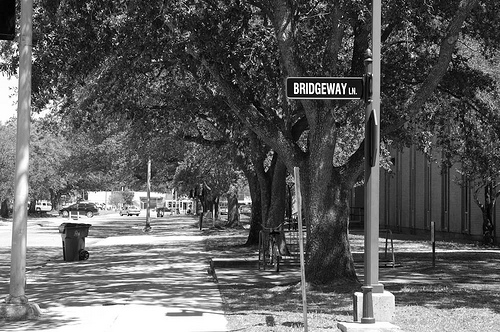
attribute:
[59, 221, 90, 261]
can — black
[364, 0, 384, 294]
post — metal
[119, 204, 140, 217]
car — parked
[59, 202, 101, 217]
car — parked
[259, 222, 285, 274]
bicycle — standing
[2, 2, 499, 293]
tree — large